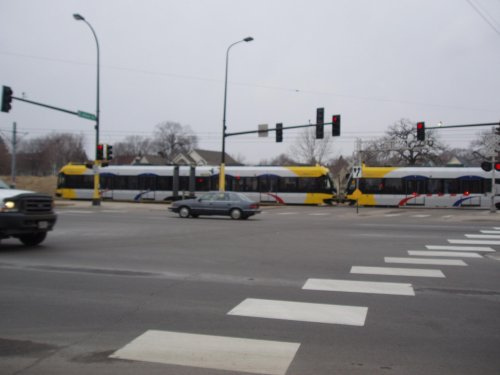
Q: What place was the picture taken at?
A: It was taken at the road.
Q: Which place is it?
A: It is a road.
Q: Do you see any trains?
A: Yes, there is a train.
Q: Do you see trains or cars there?
A: Yes, there is a train.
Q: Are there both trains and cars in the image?
A: Yes, there are both a train and cars.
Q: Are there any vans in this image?
A: No, there are no vans.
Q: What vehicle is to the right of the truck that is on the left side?
A: The vehicle is a train.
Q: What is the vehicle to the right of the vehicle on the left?
A: The vehicle is a train.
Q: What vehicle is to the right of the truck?
A: The vehicle is a train.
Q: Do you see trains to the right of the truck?
A: Yes, there is a train to the right of the truck.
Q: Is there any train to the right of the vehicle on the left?
A: Yes, there is a train to the right of the truck.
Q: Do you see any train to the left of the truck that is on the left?
A: No, the train is to the right of the truck.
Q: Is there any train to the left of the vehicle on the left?
A: No, the train is to the right of the truck.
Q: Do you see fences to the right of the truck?
A: No, there is a train to the right of the truck.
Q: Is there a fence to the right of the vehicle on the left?
A: No, there is a train to the right of the truck.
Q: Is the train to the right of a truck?
A: Yes, the train is to the right of a truck.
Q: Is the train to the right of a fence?
A: No, the train is to the right of a truck.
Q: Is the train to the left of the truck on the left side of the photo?
A: No, the train is to the right of the truck.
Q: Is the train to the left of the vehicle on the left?
A: No, the train is to the right of the truck.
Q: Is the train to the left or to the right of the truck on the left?
A: The train is to the right of the truck.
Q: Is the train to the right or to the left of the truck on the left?
A: The train is to the right of the truck.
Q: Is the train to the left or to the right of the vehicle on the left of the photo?
A: The train is to the right of the truck.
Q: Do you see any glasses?
A: No, there are no glasses.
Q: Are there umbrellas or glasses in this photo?
A: No, there are no glasses or umbrellas.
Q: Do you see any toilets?
A: No, there are no toilets.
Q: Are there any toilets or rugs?
A: No, there are no toilets or rugs.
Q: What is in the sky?
A: The clouds are in the sky.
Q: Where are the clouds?
A: The clouds are in the sky.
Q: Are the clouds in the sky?
A: Yes, the clouds are in the sky.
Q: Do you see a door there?
A: Yes, there is a door.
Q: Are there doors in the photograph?
A: Yes, there is a door.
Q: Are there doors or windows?
A: Yes, there is a door.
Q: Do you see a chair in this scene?
A: No, there are no chairs.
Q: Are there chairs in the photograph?
A: No, there are no chairs.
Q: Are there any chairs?
A: No, there are no chairs.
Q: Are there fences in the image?
A: No, there are no fences.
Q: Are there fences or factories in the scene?
A: No, there are no fences or factories.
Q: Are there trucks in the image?
A: Yes, there is a truck.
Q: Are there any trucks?
A: Yes, there is a truck.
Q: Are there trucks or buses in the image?
A: Yes, there is a truck.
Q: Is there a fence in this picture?
A: No, there are no fences.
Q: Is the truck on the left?
A: Yes, the truck is on the left of the image.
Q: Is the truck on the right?
A: No, the truck is on the left of the image.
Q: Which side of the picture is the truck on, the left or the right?
A: The truck is on the left of the image.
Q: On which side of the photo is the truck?
A: The truck is on the left of the image.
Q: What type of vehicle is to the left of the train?
A: The vehicle is a truck.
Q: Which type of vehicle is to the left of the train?
A: The vehicle is a truck.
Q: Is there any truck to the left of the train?
A: Yes, there is a truck to the left of the train.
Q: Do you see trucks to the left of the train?
A: Yes, there is a truck to the left of the train.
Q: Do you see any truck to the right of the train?
A: No, the truck is to the left of the train.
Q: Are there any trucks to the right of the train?
A: No, the truck is to the left of the train.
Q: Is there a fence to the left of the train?
A: No, there is a truck to the left of the train.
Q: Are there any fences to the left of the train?
A: No, there is a truck to the left of the train.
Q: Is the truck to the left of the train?
A: Yes, the truck is to the left of the train.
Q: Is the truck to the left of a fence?
A: No, the truck is to the left of the train.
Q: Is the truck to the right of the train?
A: No, the truck is to the left of the train.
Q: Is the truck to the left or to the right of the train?
A: The truck is to the left of the train.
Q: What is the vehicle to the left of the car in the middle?
A: The vehicle is a truck.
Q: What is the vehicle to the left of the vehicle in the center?
A: The vehicle is a truck.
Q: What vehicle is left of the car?
A: The vehicle is a truck.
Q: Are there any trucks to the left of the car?
A: Yes, there is a truck to the left of the car.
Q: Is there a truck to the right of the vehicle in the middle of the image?
A: No, the truck is to the left of the car.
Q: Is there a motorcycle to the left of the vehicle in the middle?
A: No, there is a truck to the left of the car.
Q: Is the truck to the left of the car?
A: Yes, the truck is to the left of the car.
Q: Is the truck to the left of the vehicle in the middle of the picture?
A: Yes, the truck is to the left of the car.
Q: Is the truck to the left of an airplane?
A: No, the truck is to the left of the car.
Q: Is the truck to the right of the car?
A: No, the truck is to the left of the car.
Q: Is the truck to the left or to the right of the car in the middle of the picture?
A: The truck is to the left of the car.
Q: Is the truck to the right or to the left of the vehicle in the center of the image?
A: The truck is to the left of the car.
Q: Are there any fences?
A: No, there are no fences.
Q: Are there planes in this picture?
A: No, there are no planes.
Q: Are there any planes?
A: No, there are no planes.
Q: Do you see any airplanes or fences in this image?
A: No, there are no airplanes or fences.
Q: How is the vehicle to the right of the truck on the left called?
A: The vehicle is a car.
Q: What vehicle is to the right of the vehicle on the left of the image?
A: The vehicle is a car.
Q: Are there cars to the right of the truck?
A: Yes, there is a car to the right of the truck.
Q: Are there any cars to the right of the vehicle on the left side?
A: Yes, there is a car to the right of the truck.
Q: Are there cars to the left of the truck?
A: No, the car is to the right of the truck.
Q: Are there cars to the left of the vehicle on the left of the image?
A: No, the car is to the right of the truck.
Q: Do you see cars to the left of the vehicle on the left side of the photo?
A: No, the car is to the right of the truck.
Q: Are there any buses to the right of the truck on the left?
A: No, there is a car to the right of the truck.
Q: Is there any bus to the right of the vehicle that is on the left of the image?
A: No, there is a car to the right of the truck.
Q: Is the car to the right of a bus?
A: No, the car is to the right of a truck.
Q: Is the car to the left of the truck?
A: No, the car is to the right of the truck.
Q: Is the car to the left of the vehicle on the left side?
A: No, the car is to the right of the truck.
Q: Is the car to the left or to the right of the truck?
A: The car is to the right of the truck.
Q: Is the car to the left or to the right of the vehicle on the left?
A: The car is to the right of the truck.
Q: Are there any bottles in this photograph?
A: No, there are no bottles.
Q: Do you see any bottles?
A: No, there are no bottles.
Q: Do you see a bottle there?
A: No, there are no bottles.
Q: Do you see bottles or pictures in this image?
A: No, there are no bottles or pictures.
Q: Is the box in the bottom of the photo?
A: Yes, the box is in the bottom of the image.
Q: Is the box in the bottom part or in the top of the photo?
A: The box is in the bottom of the image.